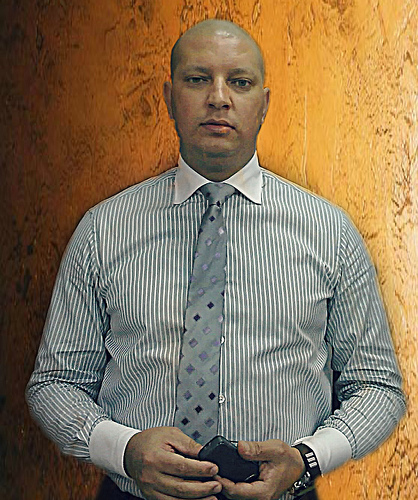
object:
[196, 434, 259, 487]
phone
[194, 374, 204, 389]
purple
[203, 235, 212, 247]
purple diamond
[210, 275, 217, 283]
diamonds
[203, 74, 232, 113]
nose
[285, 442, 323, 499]
watch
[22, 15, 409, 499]
man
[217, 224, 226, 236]
purple diamond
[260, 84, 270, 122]
left ear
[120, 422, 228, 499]
hand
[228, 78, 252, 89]
eye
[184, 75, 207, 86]
eye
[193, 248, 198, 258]
diamond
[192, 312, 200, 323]
diamond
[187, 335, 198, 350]
diamond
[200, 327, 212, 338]
diamond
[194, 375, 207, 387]
diamond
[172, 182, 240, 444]
man's tie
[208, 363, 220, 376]
diamond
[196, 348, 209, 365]
diamond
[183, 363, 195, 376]
diamond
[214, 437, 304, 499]
man's hand